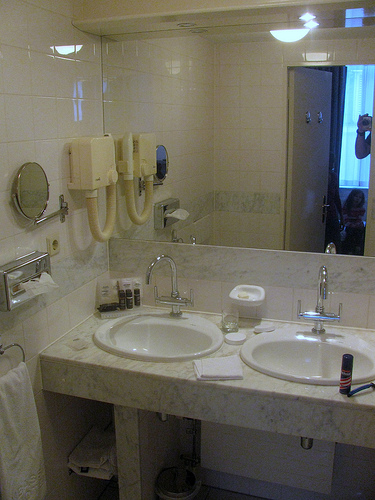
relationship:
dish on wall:
[229, 284, 265, 306] [208, 265, 288, 314]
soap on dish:
[237, 292, 250, 298] [229, 284, 265, 306]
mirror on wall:
[99, 36, 373, 255] [93, 30, 373, 312]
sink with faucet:
[96, 304, 223, 358] [140, 246, 195, 316]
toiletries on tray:
[94, 268, 144, 319] [99, 300, 146, 317]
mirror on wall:
[99, 17, 374, 256] [98, 6, 373, 327]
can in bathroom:
[161, 462, 195, 481] [1, 1, 374, 498]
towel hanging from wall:
[6, 352, 62, 434] [1, 2, 111, 498]